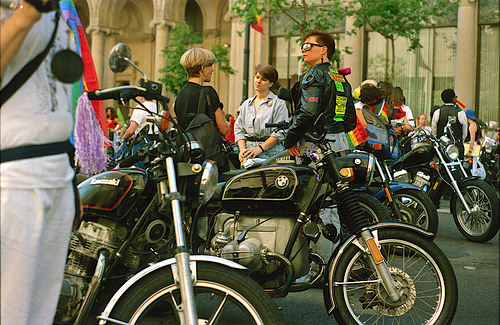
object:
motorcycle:
[79, 101, 463, 324]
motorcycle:
[218, 117, 443, 256]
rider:
[278, 31, 356, 285]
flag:
[80, 57, 133, 176]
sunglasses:
[300, 41, 324, 51]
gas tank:
[215, 157, 327, 213]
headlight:
[336, 150, 385, 186]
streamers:
[70, 92, 112, 176]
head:
[301, 27, 339, 63]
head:
[178, 46, 213, 79]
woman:
[232, 60, 289, 160]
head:
[250, 63, 278, 99]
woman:
[282, 32, 347, 170]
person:
[427, 88, 469, 144]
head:
[441, 84, 459, 111]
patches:
[333, 82, 346, 117]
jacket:
[282, 61, 358, 144]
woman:
[172, 46, 225, 171]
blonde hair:
[178, 48, 216, 68]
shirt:
[228, 90, 289, 146]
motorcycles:
[51, 37, 284, 325]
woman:
[0, 11, 111, 315]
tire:
[100, 249, 295, 324]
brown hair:
[249, 64, 278, 83]